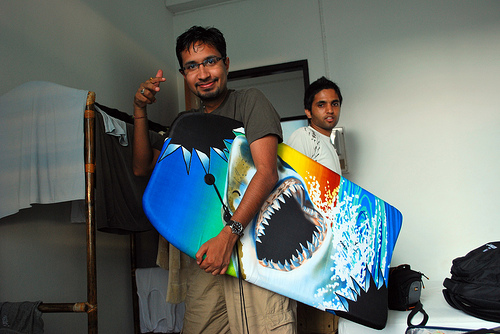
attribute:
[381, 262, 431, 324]
bag — small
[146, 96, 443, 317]
board — small, body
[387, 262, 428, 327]
lunch box — black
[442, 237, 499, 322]
bag — black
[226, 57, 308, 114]
doorway — dark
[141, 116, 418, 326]
surfboard — colorful, design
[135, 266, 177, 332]
tank top — white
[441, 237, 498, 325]
black bagpack — dark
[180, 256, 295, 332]
pants — khaki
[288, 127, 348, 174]
shirt — white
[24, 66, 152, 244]
bed — bunk, wood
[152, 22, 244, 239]
man — dark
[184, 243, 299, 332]
pants — khaki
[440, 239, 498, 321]
bookbag — black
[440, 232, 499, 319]
back pack — black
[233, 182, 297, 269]
watch — black, silver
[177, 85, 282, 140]
t-shirt — gray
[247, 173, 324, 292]
shark — white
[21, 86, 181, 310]
beds — bunk, set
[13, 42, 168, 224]
bed — bunk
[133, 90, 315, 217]
t-shirt — white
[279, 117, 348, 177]
tee shirt — white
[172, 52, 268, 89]
glasses — dark rimmed, worn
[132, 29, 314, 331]
man — gesturing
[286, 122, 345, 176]
t-shirt — white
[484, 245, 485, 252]
lettering — white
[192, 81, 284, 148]
shirt — grey